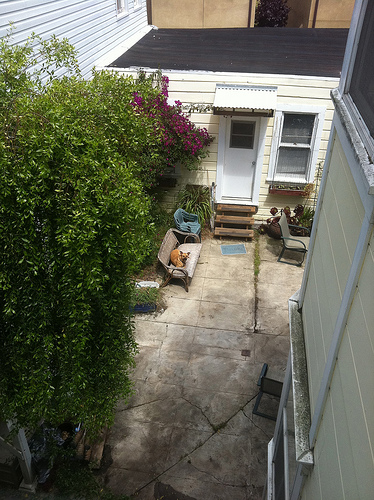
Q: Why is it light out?
A: The sun is out.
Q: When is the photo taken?
A: In the day.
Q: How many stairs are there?
A: Three.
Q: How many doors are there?
A: One.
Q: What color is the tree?
A: Green.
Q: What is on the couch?
A: An animal.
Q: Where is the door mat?
A: In front of the stairs.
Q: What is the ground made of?
A: Concrete.